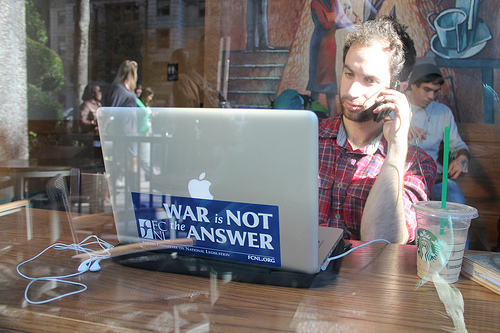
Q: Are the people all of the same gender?
A: No, they are both male and female.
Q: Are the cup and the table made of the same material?
A: No, the cup is made of plastic and the table is made of wood.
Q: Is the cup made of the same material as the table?
A: No, the cup is made of plastic and the table is made of wood.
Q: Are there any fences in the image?
A: No, there are no fences.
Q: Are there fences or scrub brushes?
A: No, there are no fences or scrub brushes.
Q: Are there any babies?
A: No, there are no babies.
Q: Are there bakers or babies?
A: No, there are no babies or bakers.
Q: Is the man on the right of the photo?
A: Yes, the man is on the right of the image.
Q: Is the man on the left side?
A: No, the man is on the right of the image.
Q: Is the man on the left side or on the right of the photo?
A: The man is on the right of the image.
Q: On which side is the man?
A: The man is on the right of the image.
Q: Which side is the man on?
A: The man is on the right of the image.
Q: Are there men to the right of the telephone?
A: Yes, there is a man to the right of the telephone.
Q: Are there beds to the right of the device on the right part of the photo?
A: No, there is a man to the right of the phone.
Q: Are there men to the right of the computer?
A: Yes, there is a man to the right of the computer.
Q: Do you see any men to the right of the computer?
A: Yes, there is a man to the right of the computer.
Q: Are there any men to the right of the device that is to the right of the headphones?
A: Yes, there is a man to the right of the computer.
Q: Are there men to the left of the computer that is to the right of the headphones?
A: No, the man is to the right of the computer.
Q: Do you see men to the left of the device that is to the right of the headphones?
A: No, the man is to the right of the computer.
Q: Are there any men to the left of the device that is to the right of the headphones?
A: No, the man is to the right of the computer.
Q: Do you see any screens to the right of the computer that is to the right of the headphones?
A: No, there is a man to the right of the computer.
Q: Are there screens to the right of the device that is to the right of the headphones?
A: No, there is a man to the right of the computer.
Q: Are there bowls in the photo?
A: No, there are no bowls.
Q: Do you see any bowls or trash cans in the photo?
A: No, there are no bowls or trash cans.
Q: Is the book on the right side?
A: Yes, the book is on the right of the image.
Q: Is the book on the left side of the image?
A: No, the book is on the right of the image.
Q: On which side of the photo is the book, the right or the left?
A: The book is on the right of the image.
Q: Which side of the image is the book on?
A: The book is on the right of the image.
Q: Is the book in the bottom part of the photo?
A: Yes, the book is in the bottom of the image.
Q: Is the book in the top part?
A: No, the book is in the bottom of the image.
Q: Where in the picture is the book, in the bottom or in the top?
A: The book is in the bottom of the image.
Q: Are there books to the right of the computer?
A: Yes, there is a book to the right of the computer.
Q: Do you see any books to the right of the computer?
A: Yes, there is a book to the right of the computer.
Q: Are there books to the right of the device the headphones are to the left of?
A: Yes, there is a book to the right of the computer.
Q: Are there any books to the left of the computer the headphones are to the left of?
A: No, the book is to the right of the computer.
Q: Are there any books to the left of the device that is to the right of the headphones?
A: No, the book is to the right of the computer.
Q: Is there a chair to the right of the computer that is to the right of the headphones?
A: No, there is a book to the right of the computer.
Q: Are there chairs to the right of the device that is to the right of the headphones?
A: No, there is a book to the right of the computer.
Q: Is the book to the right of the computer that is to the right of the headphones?
A: Yes, the book is to the right of the computer.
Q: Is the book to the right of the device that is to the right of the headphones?
A: Yes, the book is to the right of the computer.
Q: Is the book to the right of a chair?
A: No, the book is to the right of the computer.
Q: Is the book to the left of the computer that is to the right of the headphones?
A: No, the book is to the right of the computer.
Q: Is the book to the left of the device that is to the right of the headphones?
A: No, the book is to the right of the computer.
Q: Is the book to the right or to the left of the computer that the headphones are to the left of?
A: The book is to the right of the computer.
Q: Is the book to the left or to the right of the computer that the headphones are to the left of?
A: The book is to the right of the computer.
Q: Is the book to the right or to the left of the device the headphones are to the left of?
A: The book is to the right of the computer.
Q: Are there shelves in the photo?
A: No, there are no shelves.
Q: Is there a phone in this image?
A: Yes, there is a phone.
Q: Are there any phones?
A: Yes, there is a phone.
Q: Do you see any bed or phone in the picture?
A: Yes, there is a phone.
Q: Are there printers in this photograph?
A: No, there are no printers.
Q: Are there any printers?
A: No, there are no printers.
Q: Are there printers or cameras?
A: No, there are no printers or cameras.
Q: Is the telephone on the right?
A: Yes, the telephone is on the right of the image.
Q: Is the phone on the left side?
A: No, the phone is on the right of the image.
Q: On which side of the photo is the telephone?
A: The telephone is on the right of the image.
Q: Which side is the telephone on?
A: The telephone is on the right of the image.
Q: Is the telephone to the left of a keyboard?
A: No, the telephone is to the left of a man.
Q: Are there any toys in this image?
A: No, there are no toys.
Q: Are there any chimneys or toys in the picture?
A: No, there are no toys or chimneys.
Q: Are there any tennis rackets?
A: No, there are no tennis rackets.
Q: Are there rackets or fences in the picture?
A: No, there are no rackets or fences.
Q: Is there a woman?
A: Yes, there is a woman.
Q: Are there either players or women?
A: Yes, there is a woman.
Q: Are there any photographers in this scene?
A: No, there are no photographers.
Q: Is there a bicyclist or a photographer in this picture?
A: No, there are no photographers or cyclists.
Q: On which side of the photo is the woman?
A: The woman is on the left of the image.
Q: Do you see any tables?
A: Yes, there is a table.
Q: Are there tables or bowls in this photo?
A: Yes, there is a table.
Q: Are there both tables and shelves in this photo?
A: No, there is a table but no shelves.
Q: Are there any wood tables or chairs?
A: Yes, there is a wood table.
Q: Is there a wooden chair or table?
A: Yes, there is a wood table.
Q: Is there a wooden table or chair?
A: Yes, there is a wood table.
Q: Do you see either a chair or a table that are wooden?
A: Yes, the table is wooden.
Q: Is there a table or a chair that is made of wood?
A: Yes, the table is made of wood.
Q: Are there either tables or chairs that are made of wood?
A: Yes, the table is made of wood.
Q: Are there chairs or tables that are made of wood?
A: Yes, the table is made of wood.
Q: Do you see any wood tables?
A: Yes, there is a wood table.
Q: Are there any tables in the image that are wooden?
A: Yes, there is a table that is wooden.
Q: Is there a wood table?
A: Yes, there is a table that is made of wood.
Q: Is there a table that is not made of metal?
A: Yes, there is a table that is made of wood.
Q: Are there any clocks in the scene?
A: No, there are no clocks.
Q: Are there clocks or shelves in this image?
A: No, there are no clocks or shelves.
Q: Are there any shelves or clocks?
A: No, there are no clocks or shelves.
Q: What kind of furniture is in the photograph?
A: The furniture is a table.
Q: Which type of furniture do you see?
A: The furniture is a table.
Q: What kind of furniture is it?
A: The piece of furniture is a table.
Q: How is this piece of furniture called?
A: This is a table.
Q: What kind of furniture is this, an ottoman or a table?
A: This is a table.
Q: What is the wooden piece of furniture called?
A: The piece of furniture is a table.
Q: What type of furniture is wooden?
A: The furniture is a table.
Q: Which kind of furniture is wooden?
A: The furniture is a table.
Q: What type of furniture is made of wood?
A: The furniture is a table.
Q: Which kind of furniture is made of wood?
A: The furniture is a table.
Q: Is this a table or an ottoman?
A: This is a table.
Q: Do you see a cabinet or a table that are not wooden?
A: No, there is a table but it is wooden.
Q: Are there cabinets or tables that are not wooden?
A: No, there is a table but it is wooden.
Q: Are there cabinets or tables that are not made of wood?
A: No, there is a table but it is made of wood.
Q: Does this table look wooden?
A: Yes, the table is wooden.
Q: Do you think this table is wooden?
A: Yes, the table is wooden.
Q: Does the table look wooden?
A: Yes, the table is wooden.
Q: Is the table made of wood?
A: Yes, the table is made of wood.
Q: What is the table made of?
A: The table is made of wood.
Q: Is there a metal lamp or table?
A: No, there is a table but it is wooden.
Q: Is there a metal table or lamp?
A: No, there is a table but it is wooden.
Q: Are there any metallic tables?
A: No, there is a table but it is wooden.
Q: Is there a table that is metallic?
A: No, there is a table but it is wooden.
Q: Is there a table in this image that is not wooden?
A: No, there is a table but it is wooden.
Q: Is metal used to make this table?
A: No, the table is made of wood.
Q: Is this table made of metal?
A: No, the table is made of wood.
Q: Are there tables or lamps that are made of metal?
A: No, there is a table but it is made of wood.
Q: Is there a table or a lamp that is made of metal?
A: No, there is a table but it is made of wood.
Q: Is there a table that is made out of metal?
A: No, there is a table but it is made of wood.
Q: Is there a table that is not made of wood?
A: No, there is a table but it is made of wood.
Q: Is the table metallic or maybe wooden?
A: The table is wooden.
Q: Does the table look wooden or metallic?
A: The table is wooden.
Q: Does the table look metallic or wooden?
A: The table is wooden.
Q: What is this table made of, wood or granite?
A: The table is made of wood.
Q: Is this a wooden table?
A: Yes, this is a wooden table.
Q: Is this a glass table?
A: No, this is a wooden table.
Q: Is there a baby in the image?
A: No, there are no babies.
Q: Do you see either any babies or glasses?
A: No, there are no babies or glasses.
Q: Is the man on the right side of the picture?
A: Yes, the man is on the right of the image.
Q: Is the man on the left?
A: No, the man is on the right of the image.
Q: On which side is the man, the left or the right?
A: The man is on the right of the image.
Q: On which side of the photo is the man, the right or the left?
A: The man is on the right of the image.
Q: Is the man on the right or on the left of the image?
A: The man is on the right of the image.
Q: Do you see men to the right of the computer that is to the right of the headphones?
A: Yes, there is a man to the right of the computer.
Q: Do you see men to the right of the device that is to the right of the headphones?
A: Yes, there is a man to the right of the computer.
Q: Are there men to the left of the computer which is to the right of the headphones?
A: No, the man is to the right of the computer.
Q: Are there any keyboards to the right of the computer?
A: No, there is a man to the right of the computer.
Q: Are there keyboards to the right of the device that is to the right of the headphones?
A: No, there is a man to the right of the computer.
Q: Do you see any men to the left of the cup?
A: Yes, there is a man to the left of the cup.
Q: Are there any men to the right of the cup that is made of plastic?
A: No, the man is to the left of the cup.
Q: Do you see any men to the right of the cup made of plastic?
A: No, the man is to the left of the cup.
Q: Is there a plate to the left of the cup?
A: No, there is a man to the left of the cup.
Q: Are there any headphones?
A: Yes, there are headphones.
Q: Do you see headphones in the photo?
A: Yes, there are headphones.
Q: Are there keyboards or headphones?
A: Yes, there are headphones.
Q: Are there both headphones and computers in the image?
A: Yes, there are both headphones and a computer.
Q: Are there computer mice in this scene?
A: No, there are no computer mice.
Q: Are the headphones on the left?
A: Yes, the headphones are on the left of the image.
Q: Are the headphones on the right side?
A: No, the headphones are on the left of the image.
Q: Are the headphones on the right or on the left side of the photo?
A: The headphones are on the left of the image.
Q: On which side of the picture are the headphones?
A: The headphones are on the left of the image.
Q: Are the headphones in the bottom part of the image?
A: Yes, the headphones are in the bottom of the image.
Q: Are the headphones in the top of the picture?
A: No, the headphones are in the bottom of the image.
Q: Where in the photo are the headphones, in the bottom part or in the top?
A: The headphones are in the bottom of the image.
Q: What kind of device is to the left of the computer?
A: The device is headphones.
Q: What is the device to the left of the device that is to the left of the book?
A: The device is headphones.